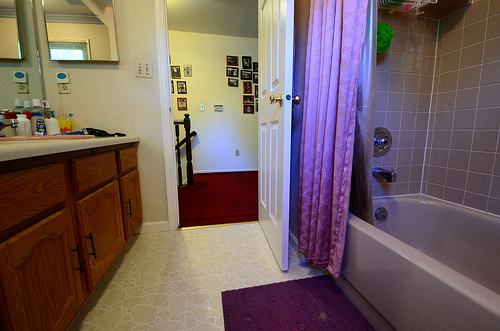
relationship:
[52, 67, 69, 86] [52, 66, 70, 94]
night light plugged into bathroom outlet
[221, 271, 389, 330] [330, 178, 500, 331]
rug next to bath tub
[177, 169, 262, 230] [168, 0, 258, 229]
carpet in hallway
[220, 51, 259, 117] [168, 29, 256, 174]
picture frames on wall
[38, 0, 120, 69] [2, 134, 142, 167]
mirror above countertop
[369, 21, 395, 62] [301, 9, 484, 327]
bath sponge in shower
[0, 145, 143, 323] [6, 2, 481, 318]
brown cabinets in bathroom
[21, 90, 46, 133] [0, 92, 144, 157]
bottle on counter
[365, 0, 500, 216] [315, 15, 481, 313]
tile in shower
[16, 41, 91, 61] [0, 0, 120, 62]
window in mirror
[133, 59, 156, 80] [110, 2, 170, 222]
light switch on wall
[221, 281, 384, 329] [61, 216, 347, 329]
rug on floor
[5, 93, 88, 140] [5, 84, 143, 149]
grooming products on counter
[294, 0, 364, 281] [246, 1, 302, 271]
curtain behind door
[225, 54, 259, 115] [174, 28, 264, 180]
picture frames on wall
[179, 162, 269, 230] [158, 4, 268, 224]
carpet in hall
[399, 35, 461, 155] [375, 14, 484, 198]
tile on wall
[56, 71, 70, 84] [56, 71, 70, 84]
night light in night light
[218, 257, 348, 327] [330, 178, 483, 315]
bath mat in front of bath tub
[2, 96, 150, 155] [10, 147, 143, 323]
counter on top of vanity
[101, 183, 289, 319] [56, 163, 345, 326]
tile on floor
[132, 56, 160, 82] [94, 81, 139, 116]
switch on wall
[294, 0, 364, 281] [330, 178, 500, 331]
curtain next to bath tub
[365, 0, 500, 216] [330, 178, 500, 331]
tile around bath tub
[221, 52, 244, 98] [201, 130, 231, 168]
posters on wall